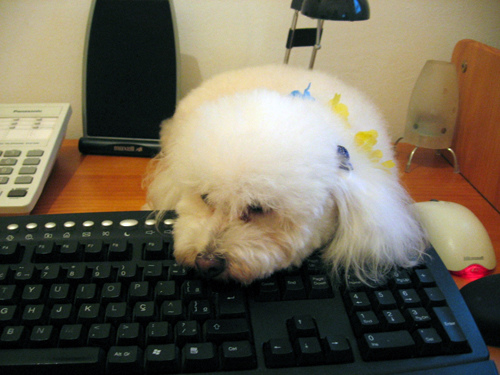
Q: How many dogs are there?
A: One.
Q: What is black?
A: Keyboard.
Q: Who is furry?
A: The dog.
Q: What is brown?
A: Desk.